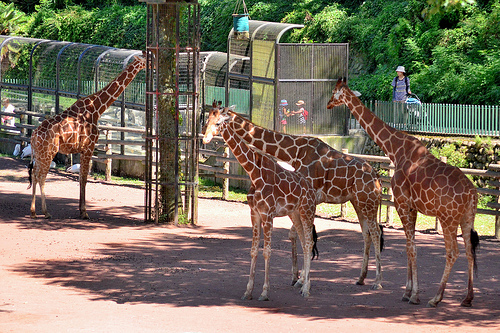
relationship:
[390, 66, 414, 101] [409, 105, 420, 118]
woman with child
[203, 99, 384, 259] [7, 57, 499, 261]
giraffes in zoo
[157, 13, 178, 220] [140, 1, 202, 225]
tree by cage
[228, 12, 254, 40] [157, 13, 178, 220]
pale from tree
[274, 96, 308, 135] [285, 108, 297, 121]
children sharing treats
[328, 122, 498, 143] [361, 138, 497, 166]
perimeter rock wall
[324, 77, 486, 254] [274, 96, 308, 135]
giraffe watching children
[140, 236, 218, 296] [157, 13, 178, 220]
shadow from tree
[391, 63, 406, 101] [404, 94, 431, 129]
person with stroller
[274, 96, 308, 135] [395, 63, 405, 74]
children wearing hat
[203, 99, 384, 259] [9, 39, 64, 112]
giraffes on pen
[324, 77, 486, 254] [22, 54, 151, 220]
giraffe by alone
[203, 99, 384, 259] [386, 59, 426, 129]
giraffes and people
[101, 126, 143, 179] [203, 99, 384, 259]
fence and giraffes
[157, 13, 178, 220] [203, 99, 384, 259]
tree for giraffes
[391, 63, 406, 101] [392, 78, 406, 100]
person with shirt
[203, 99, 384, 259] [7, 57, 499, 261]
giraffes at zoo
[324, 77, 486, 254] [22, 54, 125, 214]
giraffe standing alone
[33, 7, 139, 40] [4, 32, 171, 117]
trees behind enclosure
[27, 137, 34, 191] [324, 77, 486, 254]
tail on giraffe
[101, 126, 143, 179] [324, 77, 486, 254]
fence behind giraffe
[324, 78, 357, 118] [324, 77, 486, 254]
head of giraffe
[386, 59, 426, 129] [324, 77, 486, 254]
people at giraffe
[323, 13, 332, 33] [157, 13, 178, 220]
leaves on tree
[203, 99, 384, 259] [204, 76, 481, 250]
giraffes standing together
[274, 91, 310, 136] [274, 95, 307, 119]
two kids playing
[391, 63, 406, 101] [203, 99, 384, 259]
person watching giraffes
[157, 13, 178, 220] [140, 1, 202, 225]
tree inside cage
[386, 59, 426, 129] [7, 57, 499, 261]
people at zoo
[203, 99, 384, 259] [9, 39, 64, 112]
giraffes in pen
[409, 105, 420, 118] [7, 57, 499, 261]
child at zoo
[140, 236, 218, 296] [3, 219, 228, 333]
shadow on ground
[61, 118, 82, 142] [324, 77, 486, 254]
sunlight on giraffe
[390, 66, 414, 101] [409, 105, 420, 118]
woman beside child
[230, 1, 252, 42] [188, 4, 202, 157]
object on pole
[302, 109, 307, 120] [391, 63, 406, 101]
pack on person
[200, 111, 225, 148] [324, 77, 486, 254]
face on giraffe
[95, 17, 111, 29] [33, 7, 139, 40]
green of trees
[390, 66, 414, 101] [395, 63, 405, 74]
woman wearing hat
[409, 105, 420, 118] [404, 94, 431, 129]
child in stroller